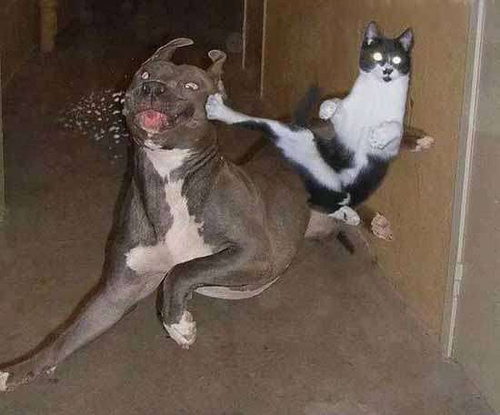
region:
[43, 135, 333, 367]
a dog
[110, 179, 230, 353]
a dog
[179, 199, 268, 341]
a dog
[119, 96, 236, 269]
a dog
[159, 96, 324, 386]
a dog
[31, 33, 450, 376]
A cat kicking a dog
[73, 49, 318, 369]
A brown dog getting kicked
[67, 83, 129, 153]
Spit from a dog's mouth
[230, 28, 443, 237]
A black and white cat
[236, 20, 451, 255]
A cat kicking it's leg out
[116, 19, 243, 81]
A dog's ears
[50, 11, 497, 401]
A black and white cat winning in a fight with a brown dog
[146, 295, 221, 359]
a dog's paw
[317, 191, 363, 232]
a cat's paw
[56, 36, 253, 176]
A dog spitting saliva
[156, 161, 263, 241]
a dog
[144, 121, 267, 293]
a dog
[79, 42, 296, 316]
The dog was kicked by the cat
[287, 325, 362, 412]
The floor is dirty in the hallway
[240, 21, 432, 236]
The cat is black and white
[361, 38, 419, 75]
The cat has reflective light in eyes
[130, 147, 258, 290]
Dog has patch of coloring on neck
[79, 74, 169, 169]
The dog is slobbering.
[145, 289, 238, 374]
Dog has white patch on foot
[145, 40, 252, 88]
Dogs ears are in the air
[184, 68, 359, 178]
Cats foot is on dogs face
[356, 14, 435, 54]
Cats ears are up in the air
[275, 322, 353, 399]
the floor is brown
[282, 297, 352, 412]
the floor is brown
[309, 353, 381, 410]
the floor is brown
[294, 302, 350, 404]
the floor is brown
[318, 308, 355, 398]
the floor is brown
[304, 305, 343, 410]
the floor is brown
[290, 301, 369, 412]
the floor is brown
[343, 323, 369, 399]
the floor is brown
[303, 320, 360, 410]
the floor is brown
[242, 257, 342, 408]
the floor is brown